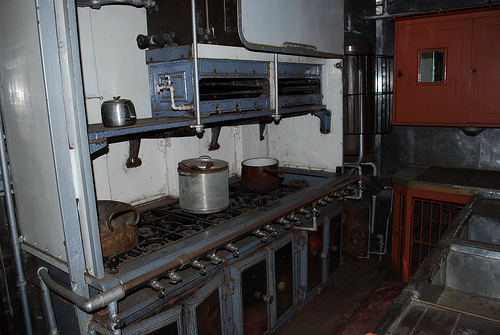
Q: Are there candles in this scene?
A: No, there are no candles.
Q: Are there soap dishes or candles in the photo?
A: No, there are no candles or soap dishes.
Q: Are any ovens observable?
A: Yes, there is an oven.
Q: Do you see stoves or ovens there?
A: Yes, there is an oven.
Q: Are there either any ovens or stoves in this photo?
A: Yes, there is an oven.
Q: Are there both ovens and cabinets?
A: Yes, there are both an oven and cabinets.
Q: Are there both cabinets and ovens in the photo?
A: Yes, there are both an oven and cabinets.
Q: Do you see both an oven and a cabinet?
A: Yes, there are both an oven and a cabinet.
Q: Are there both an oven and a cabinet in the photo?
A: Yes, there are both an oven and a cabinet.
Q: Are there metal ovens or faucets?
A: Yes, there is a metal oven.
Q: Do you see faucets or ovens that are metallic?
A: Yes, the oven is metallic.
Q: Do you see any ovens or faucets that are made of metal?
A: Yes, the oven is made of metal.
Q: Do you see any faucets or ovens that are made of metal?
A: Yes, the oven is made of metal.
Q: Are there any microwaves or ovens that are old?
A: Yes, the oven is old.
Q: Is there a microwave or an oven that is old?
A: Yes, the oven is old.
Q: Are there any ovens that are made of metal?
A: Yes, there is an oven that is made of metal.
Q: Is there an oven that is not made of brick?
A: Yes, there is an oven that is made of metal.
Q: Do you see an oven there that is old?
A: Yes, there is an oven that is old.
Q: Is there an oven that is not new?
A: Yes, there is a old oven.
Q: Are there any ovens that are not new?
A: Yes, there is a old oven.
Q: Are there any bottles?
A: No, there are no bottles.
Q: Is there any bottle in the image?
A: No, there are no bottles.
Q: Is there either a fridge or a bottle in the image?
A: No, there are no bottles or refrigerators.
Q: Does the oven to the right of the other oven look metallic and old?
A: Yes, the oven is metallic and old.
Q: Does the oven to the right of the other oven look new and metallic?
A: No, the oven is metallic but old.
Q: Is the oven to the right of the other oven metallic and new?
A: No, the oven is metallic but old.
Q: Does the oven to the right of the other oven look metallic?
A: Yes, the oven is metallic.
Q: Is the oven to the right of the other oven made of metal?
A: Yes, the oven is made of metal.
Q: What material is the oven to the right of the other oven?
A: The oven is made of metal.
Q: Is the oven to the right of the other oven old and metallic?
A: Yes, the oven is old and metallic.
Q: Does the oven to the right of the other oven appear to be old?
A: Yes, the oven is old.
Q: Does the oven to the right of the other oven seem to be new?
A: No, the oven is old.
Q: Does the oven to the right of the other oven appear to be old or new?
A: The oven is old.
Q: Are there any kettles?
A: Yes, there is a kettle.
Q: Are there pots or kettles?
A: Yes, there is a kettle.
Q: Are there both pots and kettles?
A: Yes, there are both a kettle and a pot.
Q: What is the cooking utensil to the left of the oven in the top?
A: The cooking utensil is a kettle.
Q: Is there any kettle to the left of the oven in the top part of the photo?
A: Yes, there is a kettle to the left of the oven.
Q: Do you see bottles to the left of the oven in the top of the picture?
A: No, there is a kettle to the left of the oven.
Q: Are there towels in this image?
A: No, there are no towels.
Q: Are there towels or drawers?
A: No, there are no towels or drawers.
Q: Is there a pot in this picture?
A: Yes, there is a pot.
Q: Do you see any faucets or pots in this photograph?
A: Yes, there is a pot.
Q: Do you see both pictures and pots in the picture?
A: No, there is a pot but no pictures.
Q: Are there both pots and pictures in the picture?
A: No, there is a pot but no pictures.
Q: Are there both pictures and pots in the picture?
A: No, there is a pot but no pictures.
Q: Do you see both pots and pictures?
A: No, there is a pot but no pictures.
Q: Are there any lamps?
A: No, there are no lamps.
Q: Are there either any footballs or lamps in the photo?
A: No, there are no lamps or footballs.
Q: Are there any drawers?
A: No, there are no drawers.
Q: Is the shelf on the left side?
A: Yes, the shelf is on the left of the image.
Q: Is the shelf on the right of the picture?
A: No, the shelf is on the left of the image.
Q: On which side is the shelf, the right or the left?
A: The shelf is on the left of the image.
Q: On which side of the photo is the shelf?
A: The shelf is on the left of the image.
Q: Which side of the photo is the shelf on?
A: The shelf is on the left of the image.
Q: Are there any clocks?
A: No, there are no clocks.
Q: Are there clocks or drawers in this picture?
A: No, there are no clocks or drawers.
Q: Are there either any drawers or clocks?
A: No, there are no clocks or drawers.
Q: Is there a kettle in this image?
A: Yes, there is a kettle.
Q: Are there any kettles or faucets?
A: Yes, there is a kettle.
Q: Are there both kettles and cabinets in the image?
A: Yes, there are both a kettle and cabinets.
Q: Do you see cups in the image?
A: No, there are no cups.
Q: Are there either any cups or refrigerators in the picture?
A: No, there are no cups or refrigerators.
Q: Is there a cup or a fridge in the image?
A: No, there are no cups or refrigerators.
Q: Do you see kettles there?
A: Yes, there is a kettle.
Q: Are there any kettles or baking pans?
A: Yes, there is a kettle.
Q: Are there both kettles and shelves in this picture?
A: Yes, there are both a kettle and a shelf.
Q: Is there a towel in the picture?
A: No, there are no towels.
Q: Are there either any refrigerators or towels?
A: No, there are no towels or refrigerators.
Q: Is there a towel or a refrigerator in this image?
A: No, there are no towels or refrigerators.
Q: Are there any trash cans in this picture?
A: No, there are no trash cans.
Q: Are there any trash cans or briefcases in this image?
A: No, there are no trash cans or briefcases.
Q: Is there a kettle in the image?
A: Yes, there is a kettle.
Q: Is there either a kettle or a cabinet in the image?
A: Yes, there is a kettle.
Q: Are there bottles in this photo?
A: No, there are no bottles.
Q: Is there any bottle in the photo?
A: No, there are no bottles.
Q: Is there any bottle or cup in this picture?
A: No, there are no bottles or cups.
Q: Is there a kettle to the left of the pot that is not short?
A: No, the kettle is to the right of the pot.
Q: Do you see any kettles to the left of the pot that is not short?
A: No, the kettle is to the right of the pot.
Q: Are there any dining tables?
A: No, there are no dining tables.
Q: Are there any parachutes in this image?
A: No, there are no parachutes.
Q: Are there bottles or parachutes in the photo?
A: No, there are no parachutes or bottles.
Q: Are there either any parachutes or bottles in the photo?
A: No, there are no parachutes or bottles.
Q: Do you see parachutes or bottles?
A: No, there are no parachutes or bottles.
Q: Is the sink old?
A: Yes, the sink is old.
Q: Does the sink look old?
A: Yes, the sink is old.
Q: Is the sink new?
A: No, the sink is old.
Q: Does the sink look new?
A: No, the sink is old.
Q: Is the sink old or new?
A: The sink is old.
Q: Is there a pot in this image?
A: Yes, there is a pot.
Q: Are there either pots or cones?
A: Yes, there is a pot.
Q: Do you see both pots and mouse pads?
A: No, there is a pot but no mouse pads.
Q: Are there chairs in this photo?
A: No, there are no chairs.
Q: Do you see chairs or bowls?
A: No, there are no chairs or bowls.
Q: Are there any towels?
A: No, there are no towels.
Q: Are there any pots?
A: Yes, there is a pot.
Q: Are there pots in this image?
A: Yes, there is a pot.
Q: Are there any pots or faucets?
A: Yes, there is a pot.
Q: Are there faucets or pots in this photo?
A: Yes, there is a pot.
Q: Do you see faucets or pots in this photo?
A: Yes, there is a pot.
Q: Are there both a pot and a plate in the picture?
A: No, there is a pot but no plates.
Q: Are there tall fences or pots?
A: Yes, there is a tall pot.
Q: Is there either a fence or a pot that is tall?
A: Yes, the pot is tall.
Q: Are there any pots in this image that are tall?
A: Yes, there is a tall pot.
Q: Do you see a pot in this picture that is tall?
A: Yes, there is a pot that is tall.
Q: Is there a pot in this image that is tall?
A: Yes, there is a pot that is tall.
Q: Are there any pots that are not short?
A: Yes, there is a tall pot.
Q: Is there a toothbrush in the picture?
A: No, there are no toothbrushes.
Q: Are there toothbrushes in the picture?
A: No, there are no toothbrushes.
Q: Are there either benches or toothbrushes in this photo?
A: No, there are no toothbrushes or benches.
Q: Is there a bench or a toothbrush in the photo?
A: No, there are no toothbrushes or benches.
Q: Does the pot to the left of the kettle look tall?
A: Yes, the pot is tall.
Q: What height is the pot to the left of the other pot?
A: The pot is tall.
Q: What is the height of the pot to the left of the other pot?
A: The pot is tall.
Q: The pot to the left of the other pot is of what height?
A: The pot is tall.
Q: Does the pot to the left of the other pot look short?
A: No, the pot is tall.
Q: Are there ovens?
A: Yes, there is an oven.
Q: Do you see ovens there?
A: Yes, there is an oven.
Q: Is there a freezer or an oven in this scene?
A: Yes, there is an oven.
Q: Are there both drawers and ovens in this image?
A: No, there is an oven but no drawers.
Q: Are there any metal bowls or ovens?
A: Yes, there is a metal oven.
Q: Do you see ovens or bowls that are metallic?
A: Yes, the oven is metallic.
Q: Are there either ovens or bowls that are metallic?
A: Yes, the oven is metallic.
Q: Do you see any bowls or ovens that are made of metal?
A: Yes, the oven is made of metal.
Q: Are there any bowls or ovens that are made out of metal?
A: Yes, the oven is made of metal.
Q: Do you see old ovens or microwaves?
A: Yes, there is an old oven.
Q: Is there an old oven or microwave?
A: Yes, there is an old oven.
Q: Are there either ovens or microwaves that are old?
A: Yes, the oven is old.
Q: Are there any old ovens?
A: Yes, there is an old oven.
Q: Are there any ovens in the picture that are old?
A: Yes, there is an oven that is old.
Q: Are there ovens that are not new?
A: Yes, there is a old oven.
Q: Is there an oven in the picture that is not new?
A: Yes, there is a old oven.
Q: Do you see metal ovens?
A: Yes, there is a metal oven.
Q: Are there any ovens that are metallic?
A: Yes, there is an oven that is metallic.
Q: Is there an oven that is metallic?
A: Yes, there is an oven that is metallic.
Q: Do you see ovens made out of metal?
A: Yes, there is an oven that is made of metal.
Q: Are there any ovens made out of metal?
A: Yes, there is an oven that is made of metal.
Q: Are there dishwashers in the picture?
A: No, there are no dishwashers.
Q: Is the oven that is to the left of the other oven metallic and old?
A: Yes, the oven is metallic and old.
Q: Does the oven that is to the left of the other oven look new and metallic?
A: No, the oven is metallic but old.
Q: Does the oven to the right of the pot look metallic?
A: Yes, the oven is metallic.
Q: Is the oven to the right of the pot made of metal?
A: Yes, the oven is made of metal.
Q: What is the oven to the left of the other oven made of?
A: The oven is made of metal.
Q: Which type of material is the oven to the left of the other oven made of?
A: The oven is made of metal.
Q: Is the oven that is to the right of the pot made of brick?
A: No, the oven is made of metal.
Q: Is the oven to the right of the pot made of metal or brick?
A: The oven is made of metal.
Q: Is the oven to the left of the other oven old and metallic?
A: Yes, the oven is old and metallic.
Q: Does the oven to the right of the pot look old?
A: Yes, the oven is old.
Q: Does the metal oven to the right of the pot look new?
A: No, the oven is old.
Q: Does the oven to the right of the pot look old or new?
A: The oven is old.